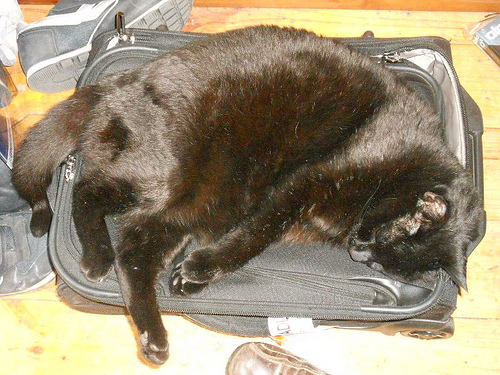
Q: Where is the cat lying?
A: On suitcase.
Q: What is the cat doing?
A: Sleeping.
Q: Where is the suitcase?
A: On the floor.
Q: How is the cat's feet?
A: Black and long.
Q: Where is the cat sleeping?
A: On the suitcase.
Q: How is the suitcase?
A: A small, black suitcase.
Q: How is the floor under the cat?
A: Wooden.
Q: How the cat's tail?
A: Black.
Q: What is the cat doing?
A: Sleeping.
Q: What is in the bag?
A: Grey shoe.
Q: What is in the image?
A: Cat.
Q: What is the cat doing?
A: Sleeping.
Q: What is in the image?
A: Black cat sleeping on a platter.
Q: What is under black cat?
A: Platter.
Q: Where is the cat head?
A: On suitcase.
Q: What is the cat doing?
A: Sleeping.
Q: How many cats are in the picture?
A: One.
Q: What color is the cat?
A: Black.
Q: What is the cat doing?
A: Sleeping.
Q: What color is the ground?
A: Brown.